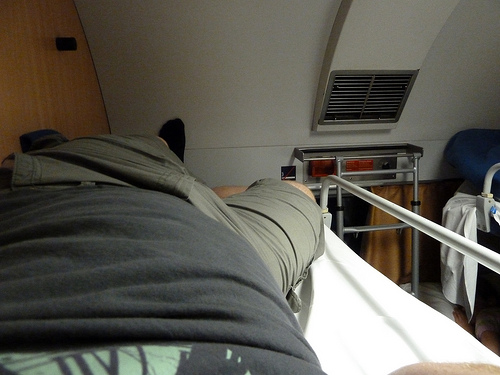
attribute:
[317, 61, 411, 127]
air vent — open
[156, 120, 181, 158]
sock — present, black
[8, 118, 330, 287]
shorts — gree, present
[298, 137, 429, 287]
ladder — silver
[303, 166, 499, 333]
rail — side, metal, silver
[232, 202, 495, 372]
sheet — present, white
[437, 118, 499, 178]
pillow — blue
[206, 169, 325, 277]
leg — present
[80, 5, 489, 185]
wall — present, arched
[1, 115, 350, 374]
man — laig, lying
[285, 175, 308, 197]
knee — white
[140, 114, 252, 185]
socks — here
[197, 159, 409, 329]
sheets — bright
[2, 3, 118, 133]
pael — wood, brow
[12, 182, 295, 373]
shirt — gre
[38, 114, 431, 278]
bed — covered